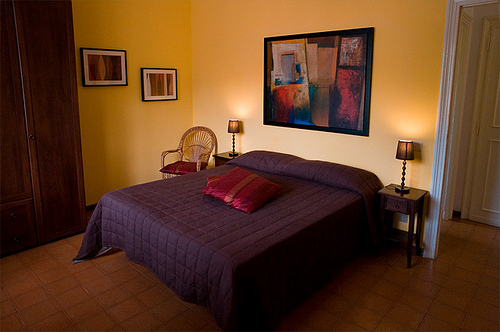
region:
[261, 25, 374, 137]
Framed modern-style painting hanging on wall.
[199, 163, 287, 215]
Two striped square pillows in center of bed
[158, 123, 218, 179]
Wicker chair with striped cushion sitting in corner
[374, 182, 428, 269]
Small wooden night stand with dark finish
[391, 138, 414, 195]
Bedside lamp with cylindrical shade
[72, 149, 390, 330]
Bed covered with dark brownish-purple spread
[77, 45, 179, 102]
Two small framed pictures with vertical designs hanging on wall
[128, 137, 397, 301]
queen size bed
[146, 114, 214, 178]
wicker chair with pillow on seat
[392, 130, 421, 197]
small lamp on nightstand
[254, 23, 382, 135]
large picture on the wall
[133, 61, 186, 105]
small picture on the wall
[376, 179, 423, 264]
small wood nightstand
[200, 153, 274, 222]
two pillows in the middle of the bed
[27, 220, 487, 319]
floor is brwon tile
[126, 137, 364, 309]
bed with purple cover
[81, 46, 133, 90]
picture with black frame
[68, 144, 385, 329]
A BED WITH A PURPLE SPREAD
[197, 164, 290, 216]
A RED PILLOW ON THE BED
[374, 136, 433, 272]
A LAMP ON A SIDE TABLE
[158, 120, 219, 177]
A WICKER CHAIR IN THE CORNER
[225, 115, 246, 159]
A TABLE LAMP WITH A BROWN SHADE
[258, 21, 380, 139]
A PICTURE HANGING OVER THE BED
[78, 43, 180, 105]
TWO PICTURES ON THE WALL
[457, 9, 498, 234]
A WHITE DOOR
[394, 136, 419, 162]
A BROWN LAMP SHADE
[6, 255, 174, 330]
A BROWN TILE FLOOR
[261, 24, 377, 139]
A painting is on the wall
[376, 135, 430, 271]
A lamp on an end table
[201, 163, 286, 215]
A red colored pillow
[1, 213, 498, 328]
Brown tiles on the floor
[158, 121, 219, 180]
Chair with a red cushion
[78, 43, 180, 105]
Two framed paintings on the wall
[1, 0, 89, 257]
A tall wooden wardrobe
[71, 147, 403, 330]
A dark purple bedspread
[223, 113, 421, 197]
Two lamp lights are turned on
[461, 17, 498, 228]
A white wooden door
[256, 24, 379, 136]
a large black picture frame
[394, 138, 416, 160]
a brown lamp shade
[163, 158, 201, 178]
a red chair pillow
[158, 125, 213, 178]
part of a chair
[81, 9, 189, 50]
part of a yellow wall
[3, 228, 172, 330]
part of a tile floor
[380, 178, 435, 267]
a brown side table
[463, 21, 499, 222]
part of a white door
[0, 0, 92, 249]
a tall brown cabinet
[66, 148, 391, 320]
a purple bedspread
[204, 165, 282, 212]
The pillows in the center of the bed.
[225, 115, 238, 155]
The lamp on the left.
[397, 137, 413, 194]
The lamp on the right.